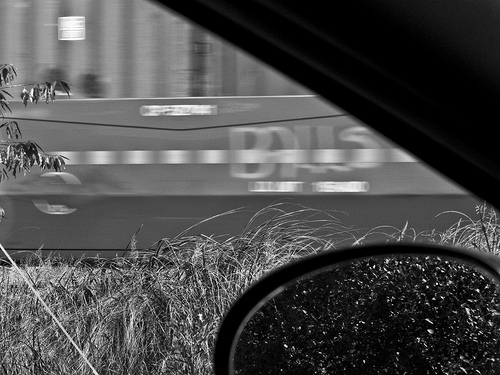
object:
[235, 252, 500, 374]
black object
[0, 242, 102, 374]
rope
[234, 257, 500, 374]
debris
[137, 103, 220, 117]
writing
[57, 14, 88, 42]
horse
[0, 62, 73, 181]
leaves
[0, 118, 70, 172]
branches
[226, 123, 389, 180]
writing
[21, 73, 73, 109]
branches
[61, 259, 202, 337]
leaves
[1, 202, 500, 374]
vegetation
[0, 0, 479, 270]
train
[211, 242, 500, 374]
mirror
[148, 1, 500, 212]
car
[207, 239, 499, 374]
frame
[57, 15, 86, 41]
sign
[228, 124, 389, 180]
graffiti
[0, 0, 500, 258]
building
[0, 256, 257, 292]
tracks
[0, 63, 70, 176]
tree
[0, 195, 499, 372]
grass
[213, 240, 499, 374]
object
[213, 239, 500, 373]
outline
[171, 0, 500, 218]
roof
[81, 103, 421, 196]
road